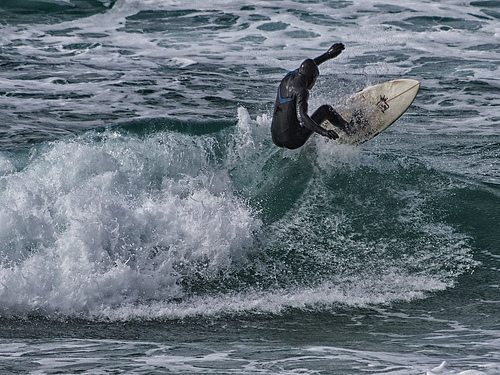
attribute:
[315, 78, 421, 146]
surfboard — white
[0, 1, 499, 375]
water — white, calm, blue, spraying, rippled, splashing, choppy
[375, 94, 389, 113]
mark — black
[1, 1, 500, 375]
foam — white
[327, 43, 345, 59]
hand — outstretched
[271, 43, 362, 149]
wetsuit — glistening, black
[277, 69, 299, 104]
mark — blue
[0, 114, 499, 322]
wave — splashing, violent, crashing, white